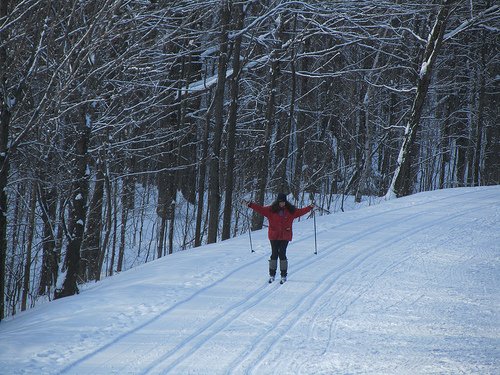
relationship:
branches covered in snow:
[124, 48, 156, 88] [187, 81, 207, 91]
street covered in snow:
[140, 276, 337, 366] [167, 321, 229, 347]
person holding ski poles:
[241, 193, 316, 284] [240, 205, 326, 266]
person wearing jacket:
[241, 193, 316, 284] [246, 202, 316, 241]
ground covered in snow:
[2, 188, 496, 369] [2, 185, 493, 374]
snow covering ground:
[2, 185, 493, 374] [2, 188, 496, 369]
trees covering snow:
[3, 0, 493, 316] [2, 185, 493, 374]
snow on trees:
[7, 1, 485, 185] [3, 0, 493, 316]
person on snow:
[241, 193, 316, 284] [2, 185, 493, 374]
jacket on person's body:
[240, 196, 318, 247] [242, 188, 322, 277]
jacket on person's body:
[246, 202, 316, 241] [250, 192, 311, 281]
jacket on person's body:
[240, 196, 318, 247] [242, 197, 312, 276]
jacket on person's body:
[240, 196, 318, 247] [250, 197, 316, 279]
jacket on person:
[246, 202, 316, 241] [241, 193, 316, 284]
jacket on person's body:
[246, 202, 316, 241] [232, 197, 330, 278]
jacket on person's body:
[240, 196, 318, 247] [242, 196, 319, 277]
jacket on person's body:
[246, 202, 316, 241] [240, 192, 316, 277]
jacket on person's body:
[246, 202, 316, 241] [235, 199, 325, 282]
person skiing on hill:
[241, 193, 316, 284] [3, 186, 493, 373]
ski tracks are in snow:
[50, 186, 492, 370] [2, 185, 493, 374]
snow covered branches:
[407, 291, 477, 353] [84, 43, 227, 177]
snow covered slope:
[372, 309, 450, 370] [37, 256, 244, 373]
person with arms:
[246, 187, 329, 283] [240, 195, 312, 216]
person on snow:
[241, 193, 316, 284] [364, 260, 439, 312]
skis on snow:
[259, 266, 289, 296] [274, 299, 385, 339]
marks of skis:
[158, 296, 292, 373] [259, 266, 289, 296]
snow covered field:
[404, 307, 451, 353] [15, 208, 484, 373]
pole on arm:
[240, 204, 268, 262] [236, 195, 323, 222]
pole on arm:
[311, 210, 323, 260] [243, 192, 319, 222]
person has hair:
[241, 193, 316, 284] [276, 182, 295, 195]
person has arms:
[241, 193, 316, 284] [232, 193, 317, 225]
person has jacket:
[241, 193, 316, 284] [246, 202, 316, 241]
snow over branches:
[335, 317, 395, 349] [155, 53, 183, 101]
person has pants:
[241, 193, 316, 284] [265, 237, 291, 278]